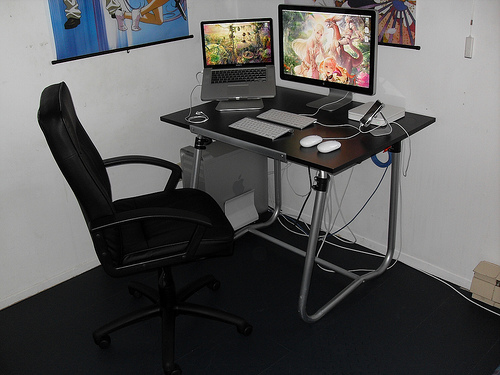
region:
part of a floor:
[397, 280, 416, 314]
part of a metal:
[298, 278, 345, 341]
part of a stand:
[211, 293, 236, 328]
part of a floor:
[381, 288, 417, 330]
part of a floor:
[388, 286, 413, 326]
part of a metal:
[305, 239, 317, 266]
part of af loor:
[338, 313, 377, 363]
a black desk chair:
[33, 79, 258, 368]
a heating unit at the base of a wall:
[467, 260, 497, 304]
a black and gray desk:
[157, 86, 444, 323]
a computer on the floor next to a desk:
[179, 132, 270, 245]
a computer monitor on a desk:
[277, 1, 380, 107]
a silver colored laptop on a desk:
[196, 17, 283, 103]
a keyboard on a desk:
[260, 103, 322, 134]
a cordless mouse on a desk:
[316, 135, 349, 155]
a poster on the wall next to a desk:
[45, 2, 196, 70]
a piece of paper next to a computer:
[224, 184, 266, 239]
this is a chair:
[48, 90, 180, 305]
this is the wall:
[436, 81, 498, 218]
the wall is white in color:
[446, 72, 499, 200]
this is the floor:
[353, 311, 451, 360]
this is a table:
[316, 149, 367, 184]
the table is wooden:
[304, 149, 339, 179]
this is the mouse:
[301, 133, 315, 144]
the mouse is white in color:
[297, 129, 315, 151]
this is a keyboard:
[244, 112, 281, 144]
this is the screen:
[276, 6, 382, 106]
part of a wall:
[456, 189, 465, 202]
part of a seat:
[178, 275, 188, 292]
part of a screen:
[350, 74, 353, 83]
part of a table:
[302, 280, 314, 305]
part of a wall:
[133, 77, 149, 99]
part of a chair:
[245, 317, 252, 328]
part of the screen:
[336, 60, 348, 69]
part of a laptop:
[218, 95, 225, 100]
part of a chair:
[342, 284, 345, 294]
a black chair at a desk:
[28, 79, 278, 361]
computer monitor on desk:
[269, 8, 394, 113]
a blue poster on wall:
[35, 2, 217, 78]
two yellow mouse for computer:
[290, 123, 358, 179]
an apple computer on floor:
[168, 125, 299, 257]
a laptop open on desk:
[196, 18, 298, 113]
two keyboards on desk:
[232, 95, 322, 172]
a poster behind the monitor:
[276, 0, 437, 60]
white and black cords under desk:
[276, 171, 425, 284]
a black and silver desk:
[160, 92, 463, 335]